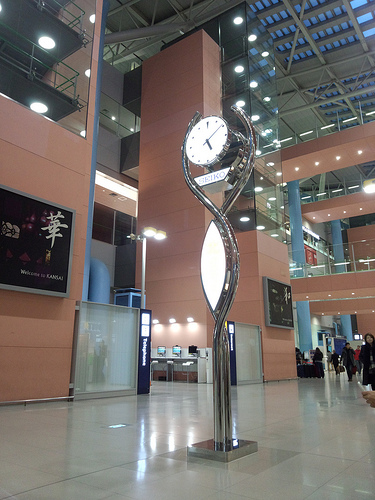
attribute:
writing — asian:
[39, 203, 68, 256]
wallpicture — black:
[8, 187, 69, 295]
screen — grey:
[233, 78, 292, 164]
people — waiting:
[294, 343, 373, 369]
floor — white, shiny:
[47, 406, 360, 481]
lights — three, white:
[235, 19, 278, 63]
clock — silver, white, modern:
[180, 116, 253, 166]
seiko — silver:
[195, 169, 225, 181]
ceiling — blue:
[117, 5, 374, 113]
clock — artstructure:
[185, 105, 246, 458]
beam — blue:
[291, 188, 322, 362]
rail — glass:
[9, 72, 93, 129]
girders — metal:
[291, 68, 374, 97]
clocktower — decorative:
[180, 107, 262, 185]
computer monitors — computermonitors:
[169, 345, 184, 355]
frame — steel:
[200, 195, 249, 453]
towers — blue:
[130, 314, 154, 388]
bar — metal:
[178, 109, 251, 443]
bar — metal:
[197, 100, 259, 447]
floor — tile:
[1, 372, 363, 494]